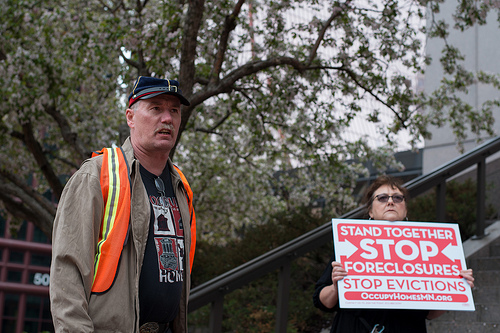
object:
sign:
[329, 217, 477, 311]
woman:
[314, 177, 477, 333]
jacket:
[49, 135, 196, 331]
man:
[49, 74, 197, 333]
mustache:
[153, 123, 174, 137]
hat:
[126, 74, 192, 108]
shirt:
[132, 162, 191, 328]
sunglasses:
[375, 193, 404, 205]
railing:
[154, 136, 500, 333]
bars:
[0, 218, 54, 331]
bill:
[140, 89, 191, 107]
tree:
[0, 0, 500, 261]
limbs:
[178, 0, 203, 91]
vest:
[92, 143, 197, 296]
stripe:
[107, 150, 120, 224]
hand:
[459, 267, 476, 287]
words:
[359, 237, 377, 260]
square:
[152, 201, 173, 239]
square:
[156, 237, 183, 279]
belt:
[134, 316, 177, 332]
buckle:
[139, 321, 161, 332]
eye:
[148, 106, 162, 111]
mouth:
[154, 128, 177, 138]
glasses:
[154, 176, 169, 209]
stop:
[361, 237, 447, 262]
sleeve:
[49, 161, 96, 333]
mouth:
[381, 209, 401, 216]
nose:
[385, 195, 397, 205]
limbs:
[11, 101, 55, 188]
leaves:
[150, 14, 181, 37]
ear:
[125, 107, 134, 129]